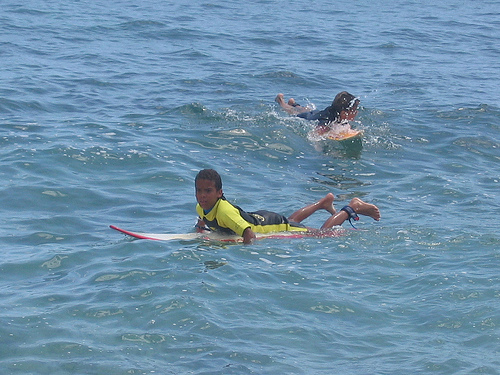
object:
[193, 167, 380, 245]
boy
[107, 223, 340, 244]
surfboard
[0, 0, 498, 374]
water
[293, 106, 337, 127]
clothing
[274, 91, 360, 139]
boy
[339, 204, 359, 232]
ankle cable